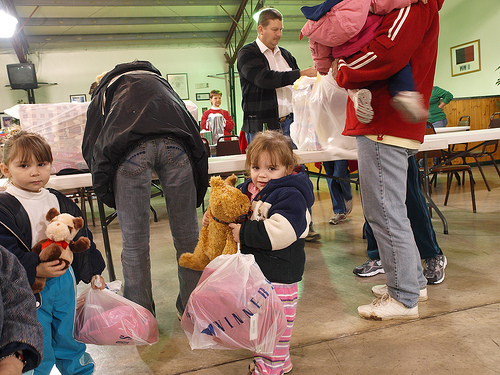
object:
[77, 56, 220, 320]
woman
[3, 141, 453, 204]
table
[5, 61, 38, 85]
tv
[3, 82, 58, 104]
stand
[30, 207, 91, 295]
animal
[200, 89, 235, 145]
boy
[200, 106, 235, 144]
shirt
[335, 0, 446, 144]
jacket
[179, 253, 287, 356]
bag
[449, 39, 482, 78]
painting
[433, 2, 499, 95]
wall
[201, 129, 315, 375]
baby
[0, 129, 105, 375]
baby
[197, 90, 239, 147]
woman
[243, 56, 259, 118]
black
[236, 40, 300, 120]
sweater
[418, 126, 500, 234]
table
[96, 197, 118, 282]
black legs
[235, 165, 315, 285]
coat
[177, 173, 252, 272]
stuffed animal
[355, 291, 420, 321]
shoe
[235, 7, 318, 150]
man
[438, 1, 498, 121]
wall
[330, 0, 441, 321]
man